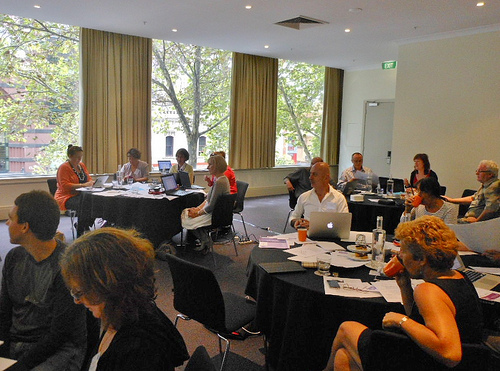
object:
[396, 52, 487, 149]
wall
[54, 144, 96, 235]
people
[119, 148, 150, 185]
people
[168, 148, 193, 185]
people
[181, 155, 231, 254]
people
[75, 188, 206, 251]
table cloth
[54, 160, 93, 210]
cardigan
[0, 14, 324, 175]
trees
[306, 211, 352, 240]
laptop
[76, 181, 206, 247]
table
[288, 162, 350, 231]
man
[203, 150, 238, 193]
woman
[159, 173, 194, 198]
laptop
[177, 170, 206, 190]
laptop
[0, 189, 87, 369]
man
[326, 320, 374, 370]
legs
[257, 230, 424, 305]
paper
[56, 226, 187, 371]
woman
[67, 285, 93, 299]
glasses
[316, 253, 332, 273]
clear cup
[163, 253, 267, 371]
chair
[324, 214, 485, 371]
lady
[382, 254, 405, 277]
cup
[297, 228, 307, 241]
cup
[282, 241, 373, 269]
pile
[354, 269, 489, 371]
dress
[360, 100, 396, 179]
door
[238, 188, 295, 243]
carpeted floor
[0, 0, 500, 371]
room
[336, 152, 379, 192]
people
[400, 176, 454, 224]
people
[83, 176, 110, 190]
laptop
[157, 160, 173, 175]
laptop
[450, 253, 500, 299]
laptop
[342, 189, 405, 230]
table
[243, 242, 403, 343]
tablecloth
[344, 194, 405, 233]
tablecloth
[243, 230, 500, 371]
table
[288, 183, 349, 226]
shirt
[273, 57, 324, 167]
window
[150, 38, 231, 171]
window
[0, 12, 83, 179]
window